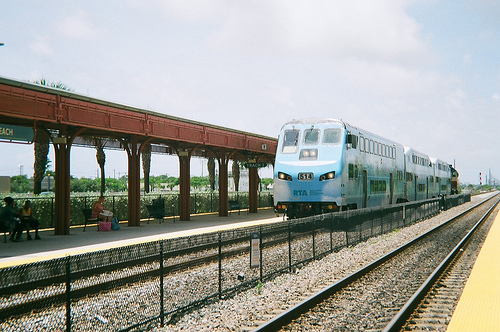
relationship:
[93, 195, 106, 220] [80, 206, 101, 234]
people on bench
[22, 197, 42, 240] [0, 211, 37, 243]
people on bench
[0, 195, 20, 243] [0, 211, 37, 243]
people on bench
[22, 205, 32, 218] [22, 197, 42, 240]
shirt on woman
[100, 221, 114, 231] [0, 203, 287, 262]
bag on ground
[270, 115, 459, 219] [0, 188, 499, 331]
train on track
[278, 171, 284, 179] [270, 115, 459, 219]
light on train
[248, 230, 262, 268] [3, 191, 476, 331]
sign on fence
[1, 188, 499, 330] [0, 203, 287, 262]
gravel on ground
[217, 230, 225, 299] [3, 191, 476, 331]
post in fence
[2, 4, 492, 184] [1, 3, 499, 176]
clouds in sky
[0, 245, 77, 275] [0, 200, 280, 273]
paint on platform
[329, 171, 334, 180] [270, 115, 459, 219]
light on train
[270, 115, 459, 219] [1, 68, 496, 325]
train entering station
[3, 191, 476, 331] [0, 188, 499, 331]
fence between tracks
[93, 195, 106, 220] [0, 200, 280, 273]
people on platform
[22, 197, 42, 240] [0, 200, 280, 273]
people on platform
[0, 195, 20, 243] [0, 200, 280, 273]
people on platform